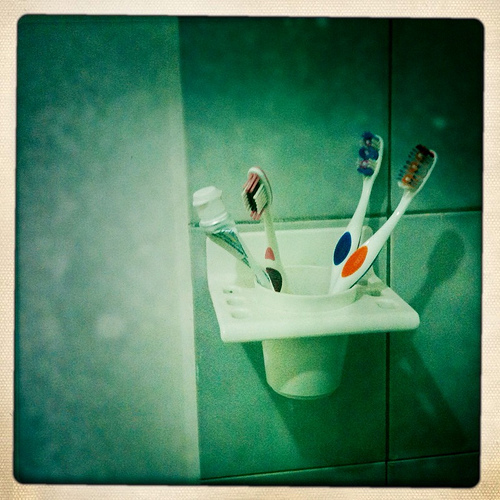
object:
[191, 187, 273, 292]
toothpaste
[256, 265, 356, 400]
holder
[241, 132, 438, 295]
brushes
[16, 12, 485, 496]
wall